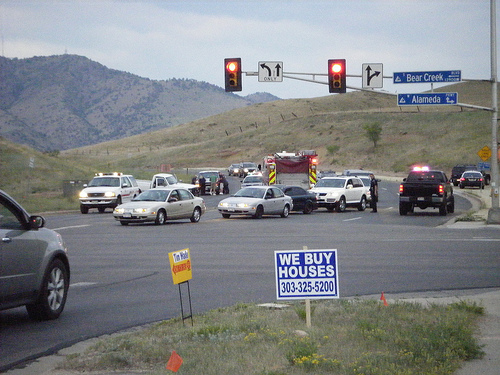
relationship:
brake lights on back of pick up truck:
[440, 186, 446, 194] [399, 170, 455, 216]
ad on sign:
[276, 253, 336, 297] [273, 250, 338, 299]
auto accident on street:
[190, 165, 232, 197] [0, 167, 499, 373]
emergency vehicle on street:
[265, 151, 315, 188] [0, 167, 499, 373]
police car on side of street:
[77, 171, 142, 213] [0, 167, 499, 373]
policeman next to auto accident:
[199, 174, 206, 193] [190, 165, 232, 197]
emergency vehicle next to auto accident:
[77, 171, 142, 213] [190, 165, 232, 197]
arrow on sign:
[172, 260, 192, 275] [168, 247, 194, 283]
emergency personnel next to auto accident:
[221, 173, 230, 194] [190, 165, 232, 197]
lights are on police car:
[95, 170, 125, 177] [77, 171, 142, 213]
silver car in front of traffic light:
[2, 187, 71, 321] [224, 63, 240, 72]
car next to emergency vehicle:
[281, 185, 318, 216] [265, 151, 315, 188]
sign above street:
[393, 71, 463, 83] [0, 167, 499, 373]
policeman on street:
[369, 173, 380, 213] [0, 167, 499, 373]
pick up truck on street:
[399, 170, 455, 216] [0, 167, 499, 373]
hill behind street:
[0, 49, 288, 151] [0, 167, 499, 373]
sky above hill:
[0, 0, 499, 100] [0, 49, 288, 151]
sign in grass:
[273, 250, 338, 299] [55, 299, 486, 374]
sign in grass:
[168, 247, 194, 283] [55, 299, 486, 374]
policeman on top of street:
[369, 173, 380, 213] [0, 167, 499, 373]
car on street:
[227, 163, 241, 176] [0, 167, 499, 373]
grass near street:
[55, 299, 486, 374] [0, 167, 499, 373]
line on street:
[48, 223, 92, 230] [0, 167, 499, 373]